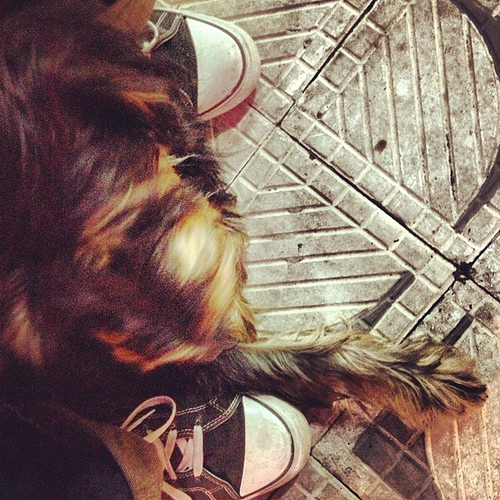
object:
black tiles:
[346, 407, 457, 498]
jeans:
[0, 400, 166, 500]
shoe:
[141, 0, 261, 125]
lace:
[118, 393, 204, 483]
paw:
[246, 327, 487, 427]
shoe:
[95, 393, 312, 500]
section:
[204, 397, 244, 497]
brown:
[2, 69, 102, 207]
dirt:
[262, 147, 403, 255]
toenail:
[464, 378, 480, 396]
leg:
[0, 389, 311, 500]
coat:
[0, 0, 488, 432]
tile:
[440, 3, 499, 96]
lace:
[139, 18, 160, 48]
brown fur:
[159, 281, 213, 343]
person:
[0, 0, 311, 500]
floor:
[145, 1, 497, 498]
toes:
[203, 29, 246, 114]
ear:
[54, 42, 186, 163]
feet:
[115, 388, 310, 500]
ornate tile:
[262, 125, 463, 316]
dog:
[0, 0, 486, 430]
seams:
[161, 389, 240, 438]